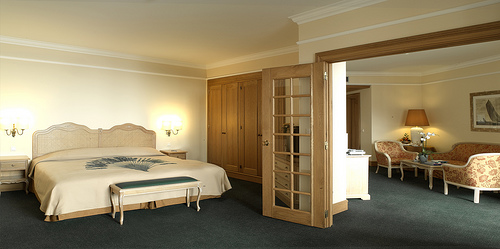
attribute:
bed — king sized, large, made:
[27, 121, 232, 221]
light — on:
[3, 110, 31, 141]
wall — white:
[2, 41, 207, 163]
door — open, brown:
[254, 61, 329, 229]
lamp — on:
[402, 106, 429, 144]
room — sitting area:
[333, 45, 500, 222]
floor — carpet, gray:
[3, 172, 498, 247]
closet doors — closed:
[205, 74, 281, 177]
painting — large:
[469, 90, 499, 131]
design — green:
[82, 155, 175, 175]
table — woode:
[397, 157, 446, 190]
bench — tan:
[106, 174, 205, 224]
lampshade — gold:
[404, 107, 431, 129]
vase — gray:
[417, 150, 428, 165]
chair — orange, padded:
[373, 139, 420, 180]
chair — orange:
[440, 149, 499, 209]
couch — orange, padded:
[426, 140, 499, 179]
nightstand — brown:
[1, 154, 33, 194]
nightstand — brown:
[159, 147, 190, 161]